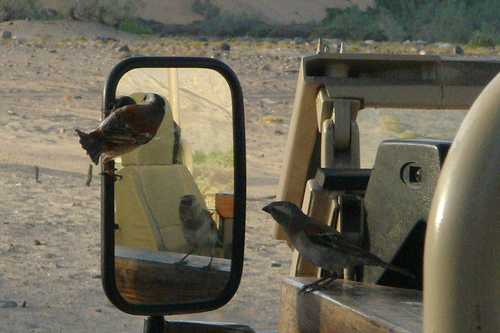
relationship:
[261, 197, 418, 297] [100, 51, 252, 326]
bird on mirror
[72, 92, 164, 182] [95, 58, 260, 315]
bird on mirror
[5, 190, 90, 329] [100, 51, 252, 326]
dirt behind mirror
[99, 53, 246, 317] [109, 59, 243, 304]
frame on mirror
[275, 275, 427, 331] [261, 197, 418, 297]
box under bird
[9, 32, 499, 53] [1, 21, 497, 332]
plants growing on ground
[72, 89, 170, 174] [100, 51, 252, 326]
bird looking in mirror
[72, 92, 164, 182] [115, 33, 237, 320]
bird hanging onto a mirror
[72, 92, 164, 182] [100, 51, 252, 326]
bird looking in mirror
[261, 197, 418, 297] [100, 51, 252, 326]
bird looking in mirror